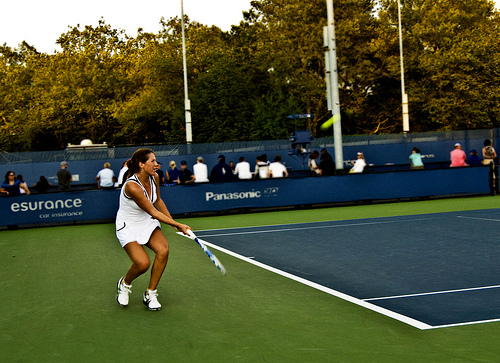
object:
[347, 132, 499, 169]
wall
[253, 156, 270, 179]
person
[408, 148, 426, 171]
person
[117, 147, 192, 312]
woman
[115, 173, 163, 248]
outfit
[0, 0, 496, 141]
trees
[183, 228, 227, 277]
racket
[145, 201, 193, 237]
hands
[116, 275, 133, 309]
shoe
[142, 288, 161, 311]
shoe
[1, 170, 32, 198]
person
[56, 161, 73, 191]
person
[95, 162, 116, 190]
person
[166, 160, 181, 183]
person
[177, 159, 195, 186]
person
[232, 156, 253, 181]
person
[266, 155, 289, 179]
person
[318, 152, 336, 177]
person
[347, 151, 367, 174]
person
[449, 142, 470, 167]
person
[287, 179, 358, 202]
wall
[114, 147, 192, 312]
person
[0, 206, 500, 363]
turf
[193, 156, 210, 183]
person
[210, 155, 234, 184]
person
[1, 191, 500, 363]
court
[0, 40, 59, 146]
tree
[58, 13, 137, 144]
tree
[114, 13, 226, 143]
tree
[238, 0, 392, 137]
tree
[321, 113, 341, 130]
ball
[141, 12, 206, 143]
tree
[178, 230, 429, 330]
boundary line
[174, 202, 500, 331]
tennis court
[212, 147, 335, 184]
benches.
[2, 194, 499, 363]
ground.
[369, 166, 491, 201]
fence.